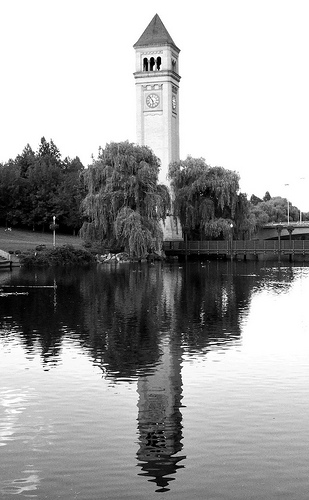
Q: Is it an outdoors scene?
A: Yes, it is outdoors.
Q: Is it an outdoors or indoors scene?
A: It is outdoors.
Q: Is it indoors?
A: No, it is outdoors.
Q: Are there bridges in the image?
A: Yes, there is a bridge.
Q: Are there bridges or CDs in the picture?
A: Yes, there is a bridge.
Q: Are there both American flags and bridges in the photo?
A: No, there is a bridge but no American flags.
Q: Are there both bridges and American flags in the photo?
A: No, there is a bridge but no American flags.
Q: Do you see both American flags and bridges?
A: No, there is a bridge but no American flags.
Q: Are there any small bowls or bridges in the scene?
A: Yes, there is a small bridge.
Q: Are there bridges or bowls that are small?
A: Yes, the bridge is small.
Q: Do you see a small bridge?
A: Yes, there is a small bridge.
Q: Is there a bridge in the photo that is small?
A: Yes, there is a bridge that is small.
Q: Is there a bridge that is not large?
A: Yes, there is a small bridge.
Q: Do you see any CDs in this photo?
A: No, there are no cds.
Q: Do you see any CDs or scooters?
A: No, there are no CDs or scooters.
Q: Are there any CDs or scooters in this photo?
A: No, there are no CDs or scooters.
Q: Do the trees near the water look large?
A: Yes, the trees are large.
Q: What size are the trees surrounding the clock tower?
A: The trees are large.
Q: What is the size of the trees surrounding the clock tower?
A: The trees are large.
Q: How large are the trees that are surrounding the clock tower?
A: The trees are large.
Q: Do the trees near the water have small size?
A: No, the trees are large.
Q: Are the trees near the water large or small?
A: The trees are large.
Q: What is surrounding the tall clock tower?
A: The trees are surrounding the clock tower.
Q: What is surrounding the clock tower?
A: The trees are surrounding the clock tower.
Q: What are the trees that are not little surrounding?
A: The trees are surrounding the clock tower.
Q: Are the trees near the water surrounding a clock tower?
A: Yes, the trees are surrounding a clock tower.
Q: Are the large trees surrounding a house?
A: No, the trees are surrounding a clock tower.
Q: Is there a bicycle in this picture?
A: No, there are no bicycles.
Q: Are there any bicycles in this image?
A: No, there are no bicycles.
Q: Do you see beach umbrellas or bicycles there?
A: No, there are no bicycles or beach umbrellas.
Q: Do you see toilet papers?
A: No, there are no toilet papers.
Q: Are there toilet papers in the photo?
A: No, there are no toilet papers.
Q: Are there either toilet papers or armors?
A: No, there are no toilet papers or armors.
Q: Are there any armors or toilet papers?
A: No, there are no toilet papers or armors.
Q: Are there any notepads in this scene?
A: No, there are no notepads.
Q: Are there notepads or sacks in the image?
A: No, there are no notepads or sacks.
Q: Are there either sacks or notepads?
A: No, there are no notepads or sacks.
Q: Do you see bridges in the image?
A: Yes, there is a bridge.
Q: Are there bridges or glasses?
A: Yes, there is a bridge.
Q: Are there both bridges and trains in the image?
A: No, there is a bridge but no trains.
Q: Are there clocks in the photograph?
A: Yes, there is a clock.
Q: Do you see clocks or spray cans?
A: Yes, there is a clock.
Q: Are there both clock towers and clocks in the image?
A: Yes, there are both a clock and a clock tower.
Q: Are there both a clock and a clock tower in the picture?
A: Yes, there are both a clock and a clock tower.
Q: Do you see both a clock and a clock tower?
A: Yes, there are both a clock and a clock tower.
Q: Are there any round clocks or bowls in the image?
A: Yes, there is a round clock.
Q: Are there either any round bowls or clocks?
A: Yes, there is a round clock.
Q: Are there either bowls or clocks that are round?
A: Yes, the clock is round.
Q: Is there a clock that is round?
A: Yes, there is a round clock.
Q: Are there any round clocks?
A: Yes, there is a round clock.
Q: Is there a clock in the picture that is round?
A: Yes, there is a clock that is round.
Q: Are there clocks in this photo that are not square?
A: Yes, there is a round clock.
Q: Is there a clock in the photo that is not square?
A: Yes, there is a round clock.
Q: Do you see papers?
A: No, there are no papers.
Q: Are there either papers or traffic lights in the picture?
A: No, there are no papers or traffic lights.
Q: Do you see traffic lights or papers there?
A: No, there are no papers or traffic lights.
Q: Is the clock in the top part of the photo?
A: Yes, the clock is in the top of the image.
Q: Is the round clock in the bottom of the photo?
A: No, the clock is in the top of the image.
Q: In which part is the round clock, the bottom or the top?
A: The clock is in the top of the image.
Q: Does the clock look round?
A: Yes, the clock is round.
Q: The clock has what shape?
A: The clock is round.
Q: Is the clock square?
A: No, the clock is round.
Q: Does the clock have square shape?
A: No, the clock is round.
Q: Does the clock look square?
A: No, the clock is round.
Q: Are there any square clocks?
A: No, there is a clock but it is round.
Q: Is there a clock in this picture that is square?
A: No, there is a clock but it is round.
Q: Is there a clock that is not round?
A: No, there is a clock but it is round.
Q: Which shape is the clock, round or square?
A: The clock is round.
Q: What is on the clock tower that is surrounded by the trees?
A: The clock is on the clock tower.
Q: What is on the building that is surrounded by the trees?
A: The clock is on the clock tower.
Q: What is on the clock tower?
A: The clock is on the clock tower.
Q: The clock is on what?
A: The clock is on the clock tower.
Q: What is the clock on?
A: The clock is on the clock tower.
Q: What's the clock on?
A: The clock is on the clock tower.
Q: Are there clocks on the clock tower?
A: Yes, there is a clock on the clock tower.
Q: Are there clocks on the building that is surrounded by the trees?
A: Yes, there is a clock on the clock tower.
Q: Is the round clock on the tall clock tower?
A: Yes, the clock is on the clock tower.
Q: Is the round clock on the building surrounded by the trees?
A: Yes, the clock is on the clock tower.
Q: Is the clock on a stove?
A: No, the clock is on the clock tower.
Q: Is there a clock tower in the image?
A: Yes, there is a clock tower.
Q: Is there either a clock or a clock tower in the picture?
A: Yes, there is a clock tower.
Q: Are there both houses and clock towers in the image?
A: No, there is a clock tower but no houses.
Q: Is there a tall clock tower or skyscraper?
A: Yes, there is a tall clock tower.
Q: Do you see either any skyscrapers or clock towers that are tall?
A: Yes, the clock tower is tall.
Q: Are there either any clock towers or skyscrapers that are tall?
A: Yes, the clock tower is tall.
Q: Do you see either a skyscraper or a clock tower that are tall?
A: Yes, the clock tower is tall.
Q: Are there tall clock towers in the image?
A: Yes, there is a tall clock tower.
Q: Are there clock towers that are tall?
A: Yes, there is a clock tower that is tall.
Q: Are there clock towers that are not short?
A: Yes, there is a tall clock tower.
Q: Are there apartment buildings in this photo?
A: No, there are no apartment buildings.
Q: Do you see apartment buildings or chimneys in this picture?
A: No, there are no apartment buildings or chimneys.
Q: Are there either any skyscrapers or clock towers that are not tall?
A: No, there is a clock tower but it is tall.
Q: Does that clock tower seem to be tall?
A: Yes, the clock tower is tall.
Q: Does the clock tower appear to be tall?
A: Yes, the clock tower is tall.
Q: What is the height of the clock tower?
A: The clock tower is tall.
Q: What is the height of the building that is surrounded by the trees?
A: The clock tower is tall.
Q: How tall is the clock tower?
A: The clock tower is tall.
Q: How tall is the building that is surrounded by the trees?
A: The clock tower is tall.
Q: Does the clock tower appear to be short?
A: No, the clock tower is tall.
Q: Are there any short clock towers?
A: No, there is a clock tower but it is tall.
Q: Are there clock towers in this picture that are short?
A: No, there is a clock tower but it is tall.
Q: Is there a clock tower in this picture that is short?
A: No, there is a clock tower but it is tall.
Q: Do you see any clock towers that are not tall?
A: No, there is a clock tower but it is tall.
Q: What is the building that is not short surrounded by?
A: The clock tower is surrounded by the trees.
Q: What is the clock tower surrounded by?
A: The clock tower is surrounded by the trees.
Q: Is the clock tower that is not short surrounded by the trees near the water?
A: Yes, the clock tower is surrounded by the trees.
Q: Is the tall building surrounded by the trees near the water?
A: Yes, the clock tower is surrounded by the trees.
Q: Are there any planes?
A: No, there are no planes.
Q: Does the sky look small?
A: Yes, the sky is small.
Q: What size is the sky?
A: The sky is small.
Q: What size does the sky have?
A: The sky has small size.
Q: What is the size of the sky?
A: The sky is small.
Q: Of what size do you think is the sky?
A: The sky is small.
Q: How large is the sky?
A: The sky is small.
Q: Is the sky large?
A: No, the sky is small.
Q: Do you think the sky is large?
A: No, the sky is small.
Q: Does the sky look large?
A: No, the sky is small.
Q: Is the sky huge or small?
A: The sky is small.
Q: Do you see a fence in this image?
A: Yes, there is a fence.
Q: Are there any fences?
A: Yes, there is a fence.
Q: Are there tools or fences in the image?
A: Yes, there is a fence.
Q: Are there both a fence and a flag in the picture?
A: No, there is a fence but no flags.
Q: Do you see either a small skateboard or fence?
A: Yes, there is a small fence.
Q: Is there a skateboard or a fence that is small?
A: Yes, the fence is small.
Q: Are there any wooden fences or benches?
A: Yes, there is a wood fence.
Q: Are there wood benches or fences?
A: Yes, there is a wood fence.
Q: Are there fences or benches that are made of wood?
A: Yes, the fence is made of wood.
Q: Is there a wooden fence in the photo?
A: Yes, there is a wood fence.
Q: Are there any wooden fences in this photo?
A: Yes, there is a wood fence.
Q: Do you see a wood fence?
A: Yes, there is a wood fence.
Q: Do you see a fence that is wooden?
A: Yes, there is a fence that is wooden.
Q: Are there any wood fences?
A: Yes, there is a fence that is made of wood.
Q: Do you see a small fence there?
A: Yes, there is a small fence.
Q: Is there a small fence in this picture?
A: Yes, there is a small fence.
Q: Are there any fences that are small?
A: Yes, there is a fence that is small.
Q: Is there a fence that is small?
A: Yes, there is a fence that is small.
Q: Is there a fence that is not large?
A: Yes, there is a small fence.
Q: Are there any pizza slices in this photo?
A: No, there are no pizza slices.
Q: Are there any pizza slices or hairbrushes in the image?
A: No, there are no pizza slices or hairbrushes.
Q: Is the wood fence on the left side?
A: Yes, the fence is on the left of the image.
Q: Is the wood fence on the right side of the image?
A: No, the fence is on the left of the image.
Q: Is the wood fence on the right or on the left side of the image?
A: The fence is on the left of the image.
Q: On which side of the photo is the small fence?
A: The fence is on the left of the image.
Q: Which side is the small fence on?
A: The fence is on the left of the image.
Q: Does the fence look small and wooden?
A: Yes, the fence is small and wooden.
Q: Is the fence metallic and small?
A: No, the fence is small but wooden.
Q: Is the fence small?
A: Yes, the fence is small.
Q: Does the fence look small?
A: Yes, the fence is small.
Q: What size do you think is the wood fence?
A: The fence is small.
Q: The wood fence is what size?
A: The fence is small.